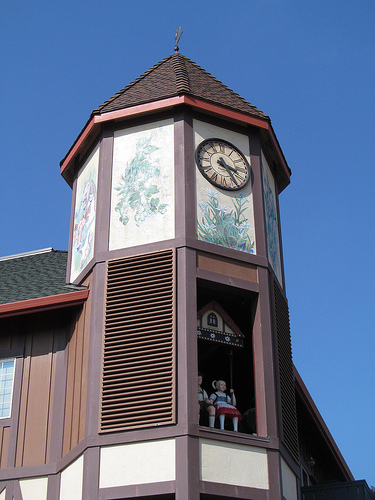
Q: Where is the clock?
A: On the tower.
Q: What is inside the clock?
A: Wooden figures.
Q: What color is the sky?
A: Blue.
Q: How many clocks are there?
A: One.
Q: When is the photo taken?
A: Daytime.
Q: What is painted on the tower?
A: Plants.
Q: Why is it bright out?
A: It is sunny.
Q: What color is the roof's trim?
A: Red.